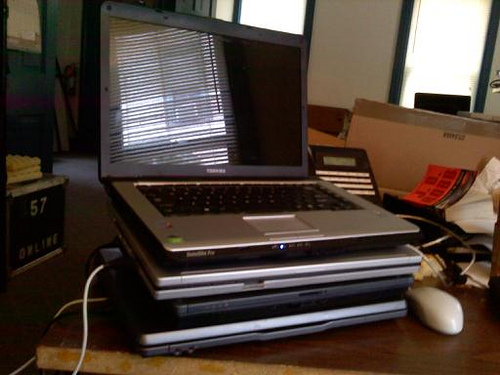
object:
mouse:
[406, 284, 464, 336]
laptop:
[93, 3, 422, 265]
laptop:
[113, 249, 426, 358]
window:
[389, 0, 500, 113]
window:
[212, 0, 308, 36]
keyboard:
[123, 181, 361, 212]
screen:
[106, 16, 302, 168]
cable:
[1, 294, 111, 373]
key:
[137, 183, 362, 212]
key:
[151, 199, 179, 212]